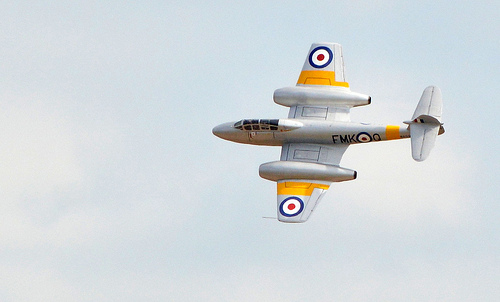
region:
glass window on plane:
[233, 117, 242, 125]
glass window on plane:
[233, 125, 246, 130]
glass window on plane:
[242, 122, 256, 130]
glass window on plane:
[248, 122, 260, 132]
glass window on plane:
[251, 117, 261, 124]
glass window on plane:
[258, 115, 267, 125]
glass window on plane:
[259, 123, 270, 133]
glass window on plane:
[268, 118, 278, 125]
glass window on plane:
[271, 123, 283, 135]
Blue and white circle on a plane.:
[280, 201, 298, 208]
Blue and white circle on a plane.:
[420, 90, 478, 135]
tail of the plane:
[395, 47, 452, 170]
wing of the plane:
[280, 184, 362, 227]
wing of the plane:
[288, 38, 345, 88]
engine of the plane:
[252, 151, 355, 185]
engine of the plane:
[261, 73, 369, 117]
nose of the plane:
[203, 117, 236, 153]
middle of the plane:
[276, 120, 390, 152]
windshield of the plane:
[223, 110, 285, 132]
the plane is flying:
[215, 38, 452, 217]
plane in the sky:
[219, 31, 464, 236]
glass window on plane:
[236, 124, 243, 130]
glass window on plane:
[243, 118, 250, 123]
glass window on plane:
[244, 123, 251, 130]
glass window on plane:
[251, 123, 259, 130]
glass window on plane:
[258, 118, 271, 124]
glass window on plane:
[258, 124, 267, 130]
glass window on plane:
[270, 116, 280, 128]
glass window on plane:
[270, 124, 277, 132]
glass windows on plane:
[232, 116, 281, 132]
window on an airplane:
[233, 117, 244, 125]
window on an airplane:
[236, 124, 243, 130]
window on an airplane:
[243, 118, 257, 123]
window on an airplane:
[243, 121, 250, 130]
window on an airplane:
[253, 122, 260, 132]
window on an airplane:
[259, 123, 271, 135]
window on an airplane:
[260, 118, 267, 125]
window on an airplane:
[268, 118, 278, 125]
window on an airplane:
[268, 125, 278, 131]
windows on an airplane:
[234, 115, 281, 134]